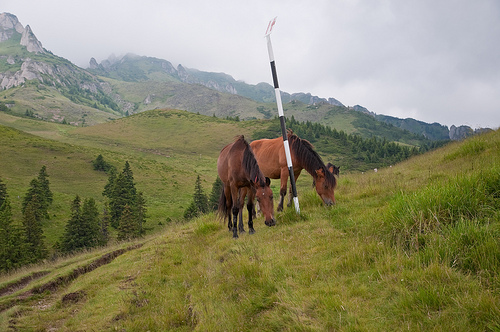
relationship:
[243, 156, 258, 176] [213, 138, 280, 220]
mane of horse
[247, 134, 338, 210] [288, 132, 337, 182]
horse with mane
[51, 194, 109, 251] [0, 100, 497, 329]
pine tree and grass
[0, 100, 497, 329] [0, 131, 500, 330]
grass all over hill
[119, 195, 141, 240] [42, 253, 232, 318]
tree is on grass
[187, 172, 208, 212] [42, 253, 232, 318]
tree is on grass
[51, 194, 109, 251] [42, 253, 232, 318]
pine tree is on grass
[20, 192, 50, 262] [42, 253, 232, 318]
tree is on grass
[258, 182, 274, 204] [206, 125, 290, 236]
spot is on horse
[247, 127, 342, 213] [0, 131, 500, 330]
horse on a hill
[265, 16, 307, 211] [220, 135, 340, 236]
pole in middle of horses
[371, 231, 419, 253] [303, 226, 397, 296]
part of grass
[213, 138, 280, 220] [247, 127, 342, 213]
horse standing beside horse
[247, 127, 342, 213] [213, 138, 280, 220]
horse standing beside horse